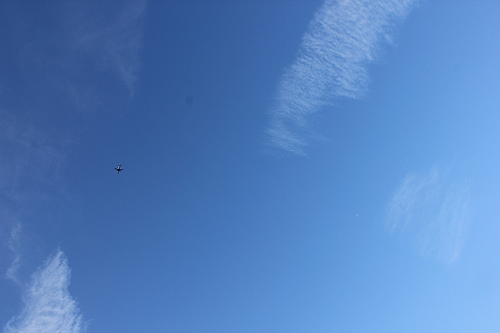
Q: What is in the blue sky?
A: A white cloud.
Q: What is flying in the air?
A: Plane.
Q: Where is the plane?
A: In the sky.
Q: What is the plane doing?
A: Flying.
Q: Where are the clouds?
A: In the sky.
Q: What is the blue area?
A: The sky.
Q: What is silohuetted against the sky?
A: The plane.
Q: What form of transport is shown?
A: Plane.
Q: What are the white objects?
A: Clouds.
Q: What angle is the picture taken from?
A: From under the plane.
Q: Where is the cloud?
A: In the sky.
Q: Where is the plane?
A: In the sky.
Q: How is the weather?
A: Clear and blue.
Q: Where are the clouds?
A: In the sky.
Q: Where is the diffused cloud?
A: In the sky.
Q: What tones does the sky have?
A: Blue.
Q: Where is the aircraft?
A: Flying in the sky.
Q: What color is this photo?
A: Blue.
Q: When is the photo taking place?
A: Daytime.